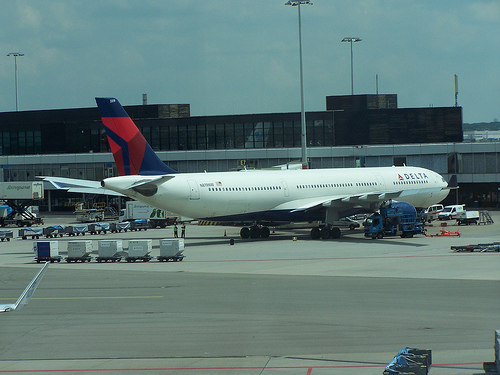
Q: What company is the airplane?
A: Delta.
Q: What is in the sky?
A: Clouds.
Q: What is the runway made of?
A: Concrete.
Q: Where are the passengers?
A: In the plane.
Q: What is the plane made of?
A: Metal.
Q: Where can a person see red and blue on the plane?
A: Tail.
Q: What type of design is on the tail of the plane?
A: Geometric.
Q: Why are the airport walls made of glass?
A: People to watch.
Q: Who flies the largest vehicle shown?
A: Pilot.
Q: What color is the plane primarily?
A: White.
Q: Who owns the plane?
A: Delta.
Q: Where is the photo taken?
A: Airport.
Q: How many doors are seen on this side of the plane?
A: Three.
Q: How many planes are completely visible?
A: One.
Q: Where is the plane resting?
A: Tarmac.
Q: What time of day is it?
A: Daytime.